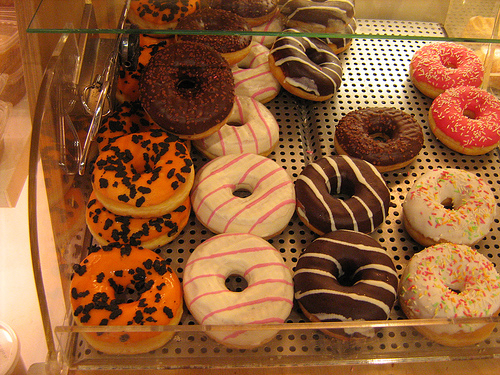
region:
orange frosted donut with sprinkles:
[71, 242, 186, 352]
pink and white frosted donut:
[185, 231, 291, 351]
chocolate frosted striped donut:
[293, 233, 398, 338]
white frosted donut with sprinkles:
[402, 242, 494, 344]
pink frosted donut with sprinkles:
[433, 84, 498, 153]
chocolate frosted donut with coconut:
[141, 41, 231, 133]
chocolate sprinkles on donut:
[68, 249, 184, 350]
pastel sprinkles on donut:
[408, 171, 495, 241]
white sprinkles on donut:
[416, 40, 484, 87]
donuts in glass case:
[75, 2, 495, 339]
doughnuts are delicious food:
[102, 29, 430, 271]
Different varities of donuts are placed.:
[106, 71, 488, 297]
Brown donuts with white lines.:
[303, 158, 381, 310]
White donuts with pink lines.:
[185, 159, 287, 326]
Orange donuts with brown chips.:
[73, 156, 180, 331]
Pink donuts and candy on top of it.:
[409, 39, 496, 156]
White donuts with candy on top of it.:
[412, 170, 487, 321]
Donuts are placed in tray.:
[121, 115, 481, 295]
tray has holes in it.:
[197, 113, 447, 263]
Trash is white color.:
[0, 322, 25, 372]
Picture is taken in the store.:
[18, 26, 497, 353]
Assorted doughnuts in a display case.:
[11, 0, 498, 374]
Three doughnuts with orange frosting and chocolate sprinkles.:
[55, 130, 193, 351]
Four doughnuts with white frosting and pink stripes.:
[191, 32, 297, 350]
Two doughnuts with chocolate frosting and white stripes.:
[292, 140, 399, 352]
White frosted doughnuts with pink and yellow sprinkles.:
[402, 157, 496, 340]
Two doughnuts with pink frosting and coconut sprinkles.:
[405, 23, 498, 158]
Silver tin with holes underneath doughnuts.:
[346, 17, 431, 104]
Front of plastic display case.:
[38, 319, 496, 370]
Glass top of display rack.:
[9, 0, 498, 46]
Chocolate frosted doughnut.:
[137, 32, 240, 144]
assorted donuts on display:
[79, 42, 486, 335]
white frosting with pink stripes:
[192, 231, 287, 328]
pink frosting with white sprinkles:
[415, 41, 495, 146]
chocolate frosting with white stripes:
[297, 228, 401, 328]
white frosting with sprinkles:
[401, 242, 491, 321]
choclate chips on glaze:
[68, 231, 170, 348]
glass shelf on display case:
[283, 16, 430, 52]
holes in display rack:
[353, 53, 398, 97]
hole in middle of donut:
[219, 264, 259, 301]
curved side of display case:
[21, 121, 59, 271]